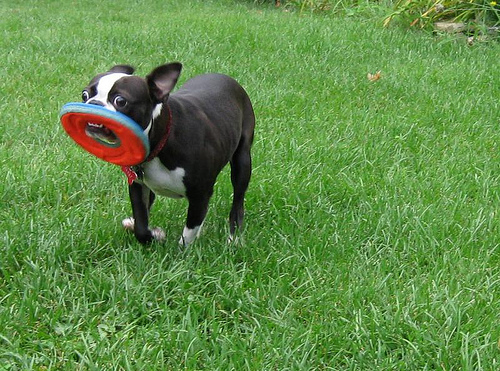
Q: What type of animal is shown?
A: Dog.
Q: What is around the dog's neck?
A: Collar.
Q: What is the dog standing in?
A: Grass.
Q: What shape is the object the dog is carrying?
A: Round.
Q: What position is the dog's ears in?
A: Up.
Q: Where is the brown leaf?
A: Behind the dog.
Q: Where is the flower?
A: Top right corner.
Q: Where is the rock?
A: Beside the flower.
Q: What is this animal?
A: Dog.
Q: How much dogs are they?
A: 1.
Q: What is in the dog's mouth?
A: Frisbee.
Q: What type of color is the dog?
A: Black and white.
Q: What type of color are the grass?
A: Green.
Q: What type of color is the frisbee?
A: Blue and red.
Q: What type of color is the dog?
A: Black and white.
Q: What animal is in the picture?
A: A dog.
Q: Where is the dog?
A: In the grass.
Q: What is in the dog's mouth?
A: A toy.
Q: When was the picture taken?
A: In the daytime.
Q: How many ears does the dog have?
A: 2.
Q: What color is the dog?
A: Black and white.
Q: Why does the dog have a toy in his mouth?
A: He is playing.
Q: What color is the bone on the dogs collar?
A: Red.